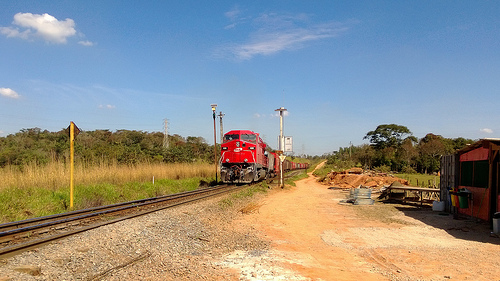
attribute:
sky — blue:
[1, 0, 497, 159]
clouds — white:
[11, 13, 78, 49]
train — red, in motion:
[220, 129, 305, 180]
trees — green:
[363, 124, 468, 175]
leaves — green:
[387, 151, 395, 158]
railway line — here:
[2, 149, 238, 275]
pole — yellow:
[69, 120, 78, 210]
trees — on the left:
[1, 126, 219, 167]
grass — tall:
[10, 161, 210, 208]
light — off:
[222, 146, 227, 149]